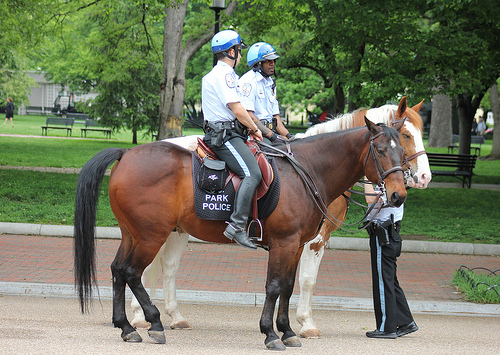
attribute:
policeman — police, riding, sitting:
[197, 24, 274, 253]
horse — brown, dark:
[69, 115, 421, 343]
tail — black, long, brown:
[71, 145, 122, 321]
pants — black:
[195, 130, 266, 177]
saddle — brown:
[195, 130, 278, 246]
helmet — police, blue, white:
[208, 28, 245, 55]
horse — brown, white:
[128, 90, 433, 341]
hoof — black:
[262, 336, 286, 353]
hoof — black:
[280, 334, 304, 349]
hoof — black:
[145, 330, 167, 346]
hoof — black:
[122, 330, 144, 343]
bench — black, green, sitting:
[40, 112, 76, 138]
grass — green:
[2, 117, 498, 243]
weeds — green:
[451, 261, 499, 308]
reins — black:
[257, 118, 377, 250]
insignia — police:
[223, 72, 237, 91]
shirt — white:
[199, 59, 243, 121]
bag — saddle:
[195, 150, 237, 221]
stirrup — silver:
[246, 220, 266, 242]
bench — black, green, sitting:
[80, 116, 115, 140]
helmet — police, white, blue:
[245, 40, 279, 65]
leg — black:
[257, 228, 304, 348]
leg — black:
[114, 227, 177, 345]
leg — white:
[293, 236, 328, 350]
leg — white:
[159, 236, 193, 336]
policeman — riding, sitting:
[236, 39, 295, 149]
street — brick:
[0, 220, 500, 317]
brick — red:
[3, 233, 499, 300]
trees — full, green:
[9, 2, 499, 186]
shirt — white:
[238, 74, 288, 127]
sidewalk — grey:
[0, 291, 499, 353]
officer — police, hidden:
[367, 179, 423, 339]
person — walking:
[474, 112, 491, 144]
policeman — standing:
[363, 173, 422, 341]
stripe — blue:
[223, 139, 252, 176]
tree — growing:
[281, 1, 498, 177]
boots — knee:
[224, 174, 263, 250]